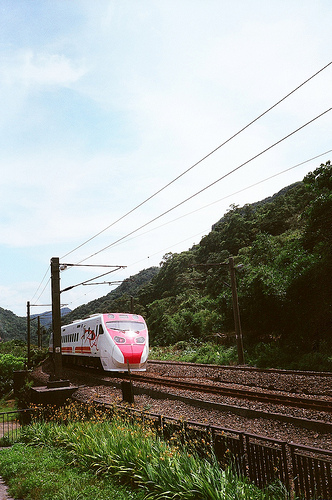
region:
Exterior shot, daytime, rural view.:
[3, 0, 321, 498]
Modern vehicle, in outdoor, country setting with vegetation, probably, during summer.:
[8, 2, 330, 499]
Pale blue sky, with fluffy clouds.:
[14, 19, 207, 148]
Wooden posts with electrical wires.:
[9, 88, 326, 331]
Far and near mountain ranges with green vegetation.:
[5, 174, 330, 354]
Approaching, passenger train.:
[59, 304, 153, 385]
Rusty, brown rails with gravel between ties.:
[179, 354, 323, 421]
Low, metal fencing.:
[104, 396, 320, 493]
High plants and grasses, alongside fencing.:
[14, 435, 231, 494]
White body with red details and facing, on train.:
[57, 313, 159, 377]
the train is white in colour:
[31, 290, 172, 392]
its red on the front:
[93, 307, 148, 377]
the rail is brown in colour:
[181, 359, 330, 419]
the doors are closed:
[80, 315, 97, 348]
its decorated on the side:
[76, 321, 106, 349]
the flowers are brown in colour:
[22, 398, 177, 475]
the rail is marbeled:
[166, 395, 269, 458]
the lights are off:
[105, 325, 144, 345]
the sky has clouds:
[21, 213, 75, 259]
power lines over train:
[92, 54, 290, 268]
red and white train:
[55, 314, 153, 363]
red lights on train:
[103, 328, 139, 357]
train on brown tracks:
[151, 372, 293, 449]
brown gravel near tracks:
[151, 371, 270, 445]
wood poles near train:
[39, 267, 86, 378]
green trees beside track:
[35, 224, 330, 399]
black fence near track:
[62, 403, 328, 479]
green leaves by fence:
[59, 421, 219, 497]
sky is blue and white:
[15, 37, 183, 166]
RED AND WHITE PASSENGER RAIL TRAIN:
[45, 308, 154, 374]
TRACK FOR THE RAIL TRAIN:
[142, 366, 331, 416]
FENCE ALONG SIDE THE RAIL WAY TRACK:
[74, 395, 330, 498]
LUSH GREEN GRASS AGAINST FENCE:
[19, 406, 272, 498]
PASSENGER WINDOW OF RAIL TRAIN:
[74, 330, 79, 342]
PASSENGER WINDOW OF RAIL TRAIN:
[73, 330, 76, 343]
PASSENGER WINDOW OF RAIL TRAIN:
[69, 334, 74, 343]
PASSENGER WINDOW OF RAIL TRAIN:
[65, 334, 71, 343]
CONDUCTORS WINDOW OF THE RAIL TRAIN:
[106, 320, 144, 333]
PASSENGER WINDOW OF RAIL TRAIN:
[58, 333, 62, 341]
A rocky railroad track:
[178, 361, 310, 437]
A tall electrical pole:
[46, 255, 72, 391]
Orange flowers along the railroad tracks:
[67, 397, 159, 442]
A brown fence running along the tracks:
[95, 399, 329, 496]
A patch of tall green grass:
[1, 446, 111, 499]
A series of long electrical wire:
[58, 170, 221, 257]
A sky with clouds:
[10, 127, 130, 203]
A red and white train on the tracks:
[47, 311, 152, 373]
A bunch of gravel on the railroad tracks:
[163, 400, 246, 426]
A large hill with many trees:
[237, 168, 330, 318]